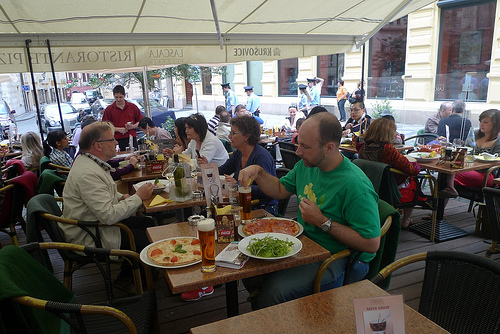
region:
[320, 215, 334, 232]
watch on man's wrist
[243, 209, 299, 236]
white plate with pizza on it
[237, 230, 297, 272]
green vegetables on plate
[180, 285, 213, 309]
red shoe on the ground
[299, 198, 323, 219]
the man's left hand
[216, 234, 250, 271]
book on the table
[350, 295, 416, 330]
menu on the table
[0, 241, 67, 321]
green jacket on the chair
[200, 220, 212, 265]
tall glass of beer on table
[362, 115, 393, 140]
the woman's blonde hair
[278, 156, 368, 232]
man wearing a green shirt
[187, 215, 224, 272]
glass of beer on a table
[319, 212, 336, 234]
man wearing a wrist watch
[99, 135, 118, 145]
man wearing black glasses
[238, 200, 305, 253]
pizza pie on a plate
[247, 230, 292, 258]
salad on a plate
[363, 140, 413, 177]
woman wearing a red shirt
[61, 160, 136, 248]
man wearing a khaki colored jacket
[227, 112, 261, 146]
woman with curly gray hair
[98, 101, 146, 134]
woman wearing a red shirt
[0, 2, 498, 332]
People at restaurant eating food.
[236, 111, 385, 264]
Man in green tea shirt squeezing lemon in drink.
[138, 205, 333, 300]
Plates of food on table.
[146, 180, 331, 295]
Drinks on brown table.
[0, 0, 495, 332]
Police walking down street outside of restaurant.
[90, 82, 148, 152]
Waiter in red shirts taking order.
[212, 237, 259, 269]
Menu on brown table.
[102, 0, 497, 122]
Lady in orange shirt standing outside restaurant.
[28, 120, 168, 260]
Man on off white shirt eating food from bowl.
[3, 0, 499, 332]
Empty chair with cane arms inside restaurant.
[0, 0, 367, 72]
tent over head the people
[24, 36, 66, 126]
two poles holding up tent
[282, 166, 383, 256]
man in green shirt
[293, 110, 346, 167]
man head looking down at table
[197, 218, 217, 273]
tall glass with liquid in it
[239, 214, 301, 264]
two plates of food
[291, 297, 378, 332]
table for sitting at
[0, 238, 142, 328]
chair for sitting on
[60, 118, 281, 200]
man and woman sitting together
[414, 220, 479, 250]
ground for holding things on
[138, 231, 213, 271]
personal pizza on a white plate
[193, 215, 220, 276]
tall glass of beer with a white foam head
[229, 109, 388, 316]
man in short sleeve green tee shirt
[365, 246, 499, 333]
partial view of a chair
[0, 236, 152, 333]
green sweater over the back of a chair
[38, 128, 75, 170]
woman with dark hair and a ponytail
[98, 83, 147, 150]
young man in a red polo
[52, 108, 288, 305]
man and woman at a table at a restaurant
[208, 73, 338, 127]
four officers in the distance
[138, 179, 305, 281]
table of food and beer